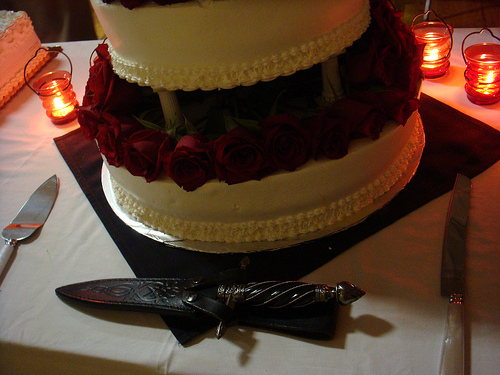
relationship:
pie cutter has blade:
[431, 168, 482, 374] [438, 169, 475, 302]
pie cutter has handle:
[431, 168, 482, 374] [435, 296, 471, 373]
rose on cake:
[161, 131, 213, 194] [85, 1, 429, 259]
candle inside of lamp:
[49, 93, 75, 122] [16, 41, 85, 126]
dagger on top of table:
[49, 249, 371, 342] [2, 9, 493, 368]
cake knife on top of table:
[431, 168, 482, 374] [2, 9, 493, 368]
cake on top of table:
[0, 1, 65, 120] [2, 9, 493, 368]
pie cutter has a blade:
[431, 168, 482, 374] [438, 169, 475, 302]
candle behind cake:
[407, 7, 453, 82] [85, 1, 429, 259]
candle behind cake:
[462, 22, 496, 105] [85, 1, 429, 259]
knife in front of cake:
[49, 249, 371, 342] [85, 1, 429, 259]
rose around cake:
[161, 131, 213, 194] [85, 1, 429, 259]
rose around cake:
[208, 123, 266, 185] [85, 1, 429, 259]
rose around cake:
[254, 111, 310, 172] [85, 1, 429, 259]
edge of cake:
[0, 7, 61, 116] [0, 1, 65, 120]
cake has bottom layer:
[85, 1, 429, 259] [85, 91, 431, 260]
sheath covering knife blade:
[49, 263, 248, 325] [49, 249, 371, 342]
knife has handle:
[431, 168, 482, 374] [435, 296, 471, 373]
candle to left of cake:
[49, 93, 75, 122] [85, 1, 429, 259]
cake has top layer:
[85, 1, 429, 259] [83, 2, 376, 94]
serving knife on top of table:
[3, 163, 63, 295] [2, 9, 493, 368]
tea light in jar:
[49, 93, 75, 122] [16, 41, 85, 126]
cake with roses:
[85, 1, 429, 259] [79, 28, 421, 190]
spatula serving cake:
[3, 163, 63, 295] [85, 1, 429, 259]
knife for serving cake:
[431, 168, 482, 374] [85, 1, 429, 259]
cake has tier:
[85, 1, 429, 259] [85, 91, 431, 260]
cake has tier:
[85, 1, 429, 259] [83, 2, 376, 94]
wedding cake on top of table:
[85, 1, 429, 259] [2, 9, 493, 368]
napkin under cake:
[36, 36, 494, 349] [85, 1, 429, 259]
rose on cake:
[208, 123, 266, 185] [85, 1, 429, 259]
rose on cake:
[254, 111, 310, 172] [85, 1, 429, 259]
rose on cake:
[302, 107, 351, 165] [85, 1, 429, 259]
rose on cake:
[328, 95, 383, 140] [85, 1, 429, 259]